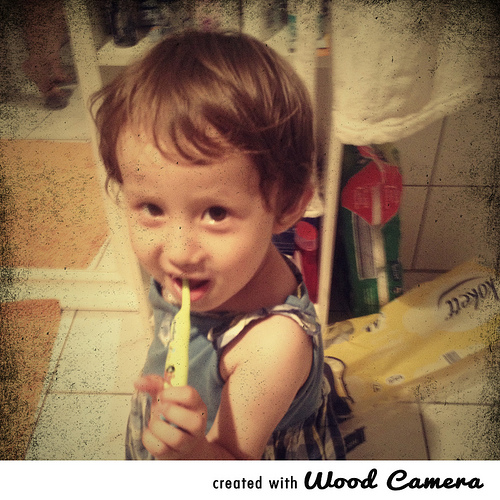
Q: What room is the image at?
A: It is at the bathroom.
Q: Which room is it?
A: It is a bathroom.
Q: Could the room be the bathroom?
A: Yes, it is the bathroom.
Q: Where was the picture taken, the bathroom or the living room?
A: It was taken at the bathroom.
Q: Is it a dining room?
A: No, it is a bathroom.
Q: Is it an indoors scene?
A: Yes, it is indoors.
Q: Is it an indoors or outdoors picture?
A: It is indoors.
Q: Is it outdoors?
A: No, it is indoors.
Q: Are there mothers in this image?
A: No, there are no mothers.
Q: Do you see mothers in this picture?
A: No, there are no mothers.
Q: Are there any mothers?
A: No, there are no mothers.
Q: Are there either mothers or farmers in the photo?
A: No, there are no mothers or farmers.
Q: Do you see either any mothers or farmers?
A: No, there are no mothers or farmers.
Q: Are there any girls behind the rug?
A: Yes, there is a girl behind the rug.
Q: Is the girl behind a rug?
A: Yes, the girl is behind a rug.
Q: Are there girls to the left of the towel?
A: Yes, there is a girl to the left of the towel.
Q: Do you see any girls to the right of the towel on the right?
A: No, the girl is to the left of the towel.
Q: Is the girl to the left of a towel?
A: Yes, the girl is to the left of a towel.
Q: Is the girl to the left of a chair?
A: No, the girl is to the left of a towel.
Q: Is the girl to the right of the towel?
A: No, the girl is to the left of the towel.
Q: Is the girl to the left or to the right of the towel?
A: The girl is to the left of the towel.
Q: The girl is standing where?
A: The girl is standing in the bathroom.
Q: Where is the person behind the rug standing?
A: The girl is standing in the bathroom.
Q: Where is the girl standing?
A: The girl is standing in the bathroom.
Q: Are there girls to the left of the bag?
A: Yes, there is a girl to the left of the bag.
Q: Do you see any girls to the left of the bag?
A: Yes, there is a girl to the left of the bag.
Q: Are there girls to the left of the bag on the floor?
A: Yes, there is a girl to the left of the bag.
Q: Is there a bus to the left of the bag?
A: No, there is a girl to the left of the bag.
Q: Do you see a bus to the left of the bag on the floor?
A: No, there is a girl to the left of the bag.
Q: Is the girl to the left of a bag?
A: Yes, the girl is to the left of a bag.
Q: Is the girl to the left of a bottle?
A: No, the girl is to the left of a bag.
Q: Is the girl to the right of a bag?
A: No, the girl is to the left of a bag.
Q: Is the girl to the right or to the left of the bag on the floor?
A: The girl is to the left of the bag.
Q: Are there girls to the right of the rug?
A: Yes, there is a girl to the right of the rug.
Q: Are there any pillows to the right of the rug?
A: No, there is a girl to the right of the rug.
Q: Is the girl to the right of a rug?
A: Yes, the girl is to the right of a rug.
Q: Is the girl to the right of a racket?
A: No, the girl is to the right of a rug.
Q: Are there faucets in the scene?
A: No, there are no faucets.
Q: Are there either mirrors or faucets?
A: No, there are no faucets or mirrors.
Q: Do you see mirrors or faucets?
A: No, there are no faucets or mirrors.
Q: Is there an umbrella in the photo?
A: No, there are no umbrellas.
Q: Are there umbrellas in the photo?
A: No, there are no umbrellas.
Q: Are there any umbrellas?
A: No, there are no umbrellas.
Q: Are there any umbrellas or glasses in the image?
A: No, there are no umbrellas or glasses.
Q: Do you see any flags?
A: No, there are no flags.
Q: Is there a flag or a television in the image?
A: No, there are no flags or televisions.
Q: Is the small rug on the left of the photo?
A: Yes, the rug is on the left of the image.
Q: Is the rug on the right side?
A: No, the rug is on the left of the image.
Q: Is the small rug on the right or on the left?
A: The rug is on the left of the image.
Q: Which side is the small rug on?
A: The rug is on the left of the image.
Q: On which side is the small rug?
A: The rug is on the left of the image.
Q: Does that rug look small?
A: Yes, the rug is small.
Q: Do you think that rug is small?
A: Yes, the rug is small.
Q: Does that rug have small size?
A: Yes, the rug is small.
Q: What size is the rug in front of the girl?
A: The rug is small.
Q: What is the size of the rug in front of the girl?
A: The rug is small.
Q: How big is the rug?
A: The rug is small.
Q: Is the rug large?
A: No, the rug is small.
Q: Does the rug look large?
A: No, the rug is small.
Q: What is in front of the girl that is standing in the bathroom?
A: The rug is in front of the girl.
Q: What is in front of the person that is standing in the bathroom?
A: The rug is in front of the girl.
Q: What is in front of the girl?
A: The rug is in front of the girl.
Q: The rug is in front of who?
A: The rug is in front of the girl.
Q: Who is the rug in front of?
A: The rug is in front of the girl.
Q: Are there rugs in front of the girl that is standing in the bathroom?
A: Yes, there is a rug in front of the girl.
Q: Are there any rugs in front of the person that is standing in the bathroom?
A: Yes, there is a rug in front of the girl.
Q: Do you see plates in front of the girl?
A: No, there is a rug in front of the girl.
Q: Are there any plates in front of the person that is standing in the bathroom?
A: No, there is a rug in front of the girl.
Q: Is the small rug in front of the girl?
A: Yes, the rug is in front of the girl.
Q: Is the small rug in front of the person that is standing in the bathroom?
A: Yes, the rug is in front of the girl.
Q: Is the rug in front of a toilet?
A: No, the rug is in front of the girl.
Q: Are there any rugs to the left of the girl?
A: Yes, there is a rug to the left of the girl.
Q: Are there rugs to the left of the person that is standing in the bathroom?
A: Yes, there is a rug to the left of the girl.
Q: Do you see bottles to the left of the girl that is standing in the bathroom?
A: No, there is a rug to the left of the girl.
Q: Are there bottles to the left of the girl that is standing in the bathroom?
A: No, there is a rug to the left of the girl.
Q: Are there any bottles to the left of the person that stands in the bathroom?
A: No, there is a rug to the left of the girl.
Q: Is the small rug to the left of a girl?
A: Yes, the rug is to the left of a girl.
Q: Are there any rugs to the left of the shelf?
A: Yes, there is a rug to the left of the shelf.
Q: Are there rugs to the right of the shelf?
A: No, the rug is to the left of the shelf.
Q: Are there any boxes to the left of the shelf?
A: No, there is a rug to the left of the shelf.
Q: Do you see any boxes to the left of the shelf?
A: No, there is a rug to the left of the shelf.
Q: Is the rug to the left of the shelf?
A: Yes, the rug is to the left of the shelf.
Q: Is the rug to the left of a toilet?
A: No, the rug is to the left of the shelf.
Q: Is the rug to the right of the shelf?
A: No, the rug is to the left of the shelf.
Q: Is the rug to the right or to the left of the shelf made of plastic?
A: The rug is to the left of the shelf.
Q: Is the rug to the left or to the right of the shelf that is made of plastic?
A: The rug is to the left of the shelf.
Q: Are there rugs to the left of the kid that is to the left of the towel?
A: Yes, there is a rug to the left of the kid.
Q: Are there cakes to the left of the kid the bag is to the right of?
A: No, there is a rug to the left of the child.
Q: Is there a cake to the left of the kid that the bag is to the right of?
A: No, there is a rug to the left of the child.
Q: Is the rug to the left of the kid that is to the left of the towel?
A: Yes, the rug is to the left of the kid.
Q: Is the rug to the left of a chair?
A: No, the rug is to the left of the kid.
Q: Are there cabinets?
A: No, there are no cabinets.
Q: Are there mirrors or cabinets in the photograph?
A: No, there are no cabinets or mirrors.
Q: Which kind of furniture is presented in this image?
A: The furniture is a shelf.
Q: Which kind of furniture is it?
A: The piece of furniture is a shelf.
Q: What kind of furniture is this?
A: This is a shelf.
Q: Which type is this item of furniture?
A: This is a shelf.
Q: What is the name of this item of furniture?
A: This is a shelf.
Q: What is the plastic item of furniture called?
A: The piece of furniture is a shelf.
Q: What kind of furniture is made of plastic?
A: The furniture is a shelf.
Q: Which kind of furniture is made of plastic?
A: The furniture is a shelf.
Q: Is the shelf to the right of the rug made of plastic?
A: Yes, the shelf is made of plastic.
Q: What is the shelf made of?
A: The shelf is made of plastic.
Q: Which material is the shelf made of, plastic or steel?
A: The shelf is made of plastic.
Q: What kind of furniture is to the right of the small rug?
A: The piece of furniture is a shelf.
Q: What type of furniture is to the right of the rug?
A: The piece of furniture is a shelf.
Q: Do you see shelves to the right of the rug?
A: Yes, there is a shelf to the right of the rug.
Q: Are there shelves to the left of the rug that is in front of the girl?
A: No, the shelf is to the right of the rug.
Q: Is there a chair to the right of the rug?
A: No, there is a shelf to the right of the rug.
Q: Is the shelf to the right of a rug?
A: Yes, the shelf is to the right of a rug.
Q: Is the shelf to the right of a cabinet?
A: No, the shelf is to the right of a rug.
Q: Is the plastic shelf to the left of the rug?
A: No, the shelf is to the right of the rug.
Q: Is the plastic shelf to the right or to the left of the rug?
A: The shelf is to the right of the rug.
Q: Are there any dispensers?
A: No, there are no dispensers.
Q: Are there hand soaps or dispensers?
A: No, there are no dispensers or hand soaps.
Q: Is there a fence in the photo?
A: No, there are no fences.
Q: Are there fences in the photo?
A: No, there are no fences.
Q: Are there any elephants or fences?
A: No, there are no fences or elephants.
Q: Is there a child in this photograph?
A: Yes, there is a child.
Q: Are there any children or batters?
A: Yes, there is a child.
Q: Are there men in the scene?
A: No, there are no men.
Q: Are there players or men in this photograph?
A: No, there are no men or players.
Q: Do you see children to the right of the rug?
A: Yes, there is a child to the right of the rug.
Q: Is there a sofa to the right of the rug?
A: No, there is a child to the right of the rug.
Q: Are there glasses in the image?
A: No, there are no glasses.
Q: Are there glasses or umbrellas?
A: No, there are no glasses or umbrellas.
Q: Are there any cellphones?
A: No, there are no cellphones.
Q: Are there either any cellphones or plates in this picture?
A: No, there are no cellphones or plates.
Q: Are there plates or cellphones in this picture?
A: No, there are no cellphones or plates.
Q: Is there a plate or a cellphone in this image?
A: No, there are no cell phones or plates.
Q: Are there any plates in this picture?
A: No, there are no plates.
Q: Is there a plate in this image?
A: No, there are no plates.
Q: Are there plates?
A: No, there are no plates.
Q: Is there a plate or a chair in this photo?
A: No, there are no plates or chairs.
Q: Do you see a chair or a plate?
A: No, there are no plates or chairs.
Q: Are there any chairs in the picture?
A: No, there are no chairs.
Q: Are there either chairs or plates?
A: No, there are no chairs or plates.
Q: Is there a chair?
A: No, there are no chairs.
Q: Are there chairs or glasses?
A: No, there are no chairs or glasses.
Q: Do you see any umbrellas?
A: No, there are no umbrellas.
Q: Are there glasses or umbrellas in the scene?
A: No, there are no umbrellas or glasses.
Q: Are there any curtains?
A: No, there are no curtains.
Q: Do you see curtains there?
A: No, there are no curtains.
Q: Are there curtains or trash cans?
A: No, there are no curtains or trash cans.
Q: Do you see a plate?
A: No, there are no plates.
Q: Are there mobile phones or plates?
A: No, there are no plates or mobile phones.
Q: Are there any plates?
A: No, there are no plates.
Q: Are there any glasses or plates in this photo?
A: No, there are no plates or glasses.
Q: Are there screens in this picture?
A: No, there are no screens.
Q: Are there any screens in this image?
A: No, there are no screens.